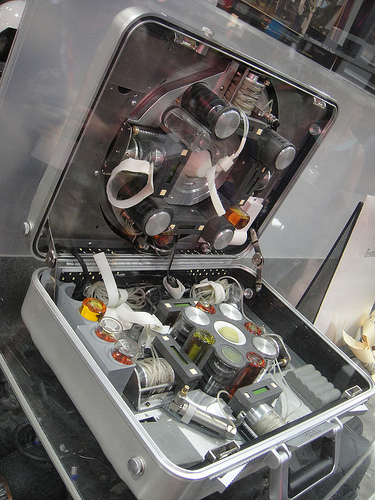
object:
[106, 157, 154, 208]
taped pieces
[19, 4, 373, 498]
gray suitcase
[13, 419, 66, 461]
wires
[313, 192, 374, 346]
white board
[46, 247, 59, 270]
hinge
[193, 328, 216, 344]
pieces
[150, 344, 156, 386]
wires